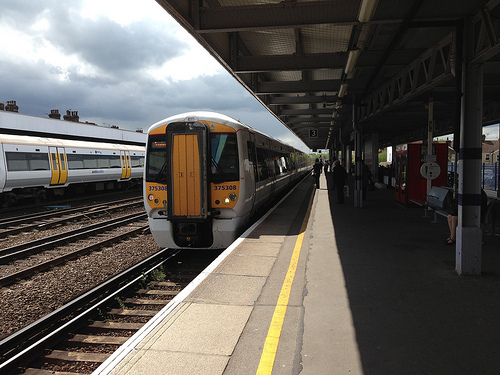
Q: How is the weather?
A: Overcast.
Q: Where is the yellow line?
A: Floor of the train station.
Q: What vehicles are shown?
A: Trains.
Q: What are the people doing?
A: Waiting for trains.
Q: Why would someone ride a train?
A: Transportation.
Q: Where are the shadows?
A: On the ground.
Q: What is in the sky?
A: Clouds.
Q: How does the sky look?
A: Overcast.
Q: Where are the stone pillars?
A: In the train station.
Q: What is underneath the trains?
A: Train tracks.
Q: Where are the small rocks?
A: On the train tracks.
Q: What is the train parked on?
A: The tracks.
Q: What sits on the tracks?
A: A train.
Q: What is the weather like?
A: Cloudy.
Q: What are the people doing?
A: Waiting for a train.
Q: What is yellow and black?
A: The train.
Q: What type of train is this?
A: A passenger train.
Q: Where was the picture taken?
A: Train station.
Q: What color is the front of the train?
A: Yellow.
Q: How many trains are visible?
A: Two.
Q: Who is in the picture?
A: Commuters.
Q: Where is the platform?
A: Right.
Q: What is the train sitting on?
A: Tracks.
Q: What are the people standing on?
A: Platform.